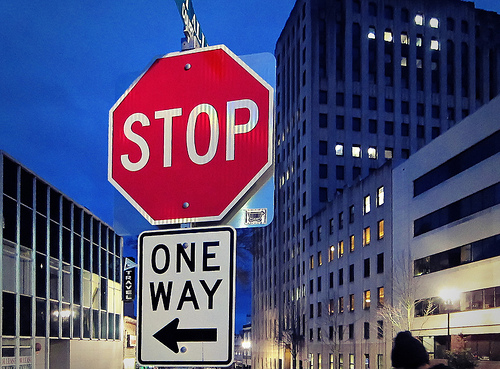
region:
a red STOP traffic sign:
[103, 46, 275, 227]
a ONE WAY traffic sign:
[136, 229, 233, 366]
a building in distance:
[0, 153, 124, 367]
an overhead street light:
[437, 287, 459, 353]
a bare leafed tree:
[270, 312, 307, 367]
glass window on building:
[378, 221, 385, 240]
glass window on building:
[376, 250, 385, 273]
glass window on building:
[377, 285, 383, 307]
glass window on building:
[378, 320, 385, 340]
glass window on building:
[362, 192, 370, 213]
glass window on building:
[361, 226, 371, 247]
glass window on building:
[363, 253, 368, 279]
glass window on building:
[363, 288, 371, 310]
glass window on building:
[363, 320, 370, 338]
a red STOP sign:
[110, 60, 266, 214]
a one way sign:
[117, 208, 254, 367]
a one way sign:
[142, 229, 224, 348]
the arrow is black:
[148, 311, 223, 350]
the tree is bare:
[362, 260, 428, 326]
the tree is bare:
[363, 248, 454, 358]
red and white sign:
[77, 38, 282, 211]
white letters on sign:
[96, 97, 264, 187]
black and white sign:
[124, 210, 255, 355]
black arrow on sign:
[141, 305, 222, 356]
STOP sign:
[106, 40, 275, 234]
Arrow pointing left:
[152, 312, 216, 354]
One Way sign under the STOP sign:
[136, 228, 237, 367]